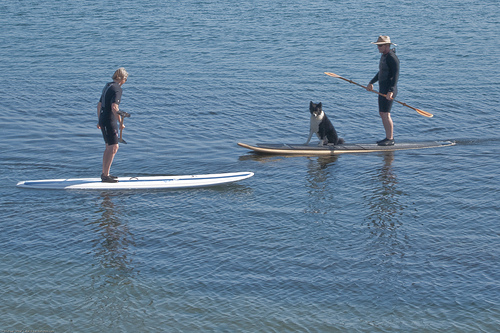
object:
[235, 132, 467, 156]
surfboard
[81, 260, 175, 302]
ripples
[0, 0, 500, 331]
water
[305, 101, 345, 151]
dog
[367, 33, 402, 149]
man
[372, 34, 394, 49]
hat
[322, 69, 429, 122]
paddle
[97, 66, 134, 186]
man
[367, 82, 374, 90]
hand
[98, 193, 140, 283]
reflection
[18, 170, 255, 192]
surfboards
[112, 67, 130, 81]
hair